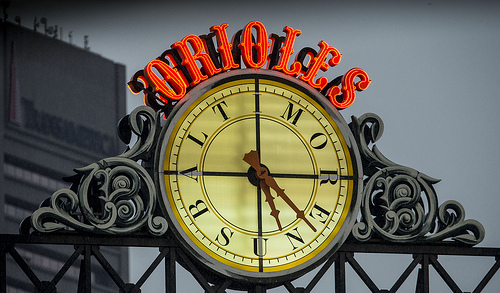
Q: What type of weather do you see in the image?
A: It is cloudy.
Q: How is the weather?
A: It is cloudy.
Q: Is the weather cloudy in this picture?
A: Yes, it is cloudy.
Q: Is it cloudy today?
A: Yes, it is cloudy.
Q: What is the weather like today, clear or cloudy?
A: It is cloudy.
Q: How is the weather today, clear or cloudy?
A: It is cloudy.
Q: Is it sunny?
A: No, it is cloudy.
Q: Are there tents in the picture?
A: No, there are no tents.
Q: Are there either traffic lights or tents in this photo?
A: No, there are no tents or traffic lights.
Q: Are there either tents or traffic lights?
A: No, there are no tents or traffic lights.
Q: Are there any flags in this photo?
A: No, there are no flags.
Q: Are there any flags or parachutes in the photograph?
A: No, there are no flags or parachutes.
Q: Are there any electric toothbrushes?
A: No, there are no electric toothbrushes.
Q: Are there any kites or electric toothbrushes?
A: No, there are no electric toothbrushes or kites.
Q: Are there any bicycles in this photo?
A: No, there are no bicycles.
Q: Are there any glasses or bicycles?
A: No, there are no bicycles or glasses.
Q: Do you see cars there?
A: No, there are no cars.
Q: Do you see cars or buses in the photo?
A: No, there are no cars or buses.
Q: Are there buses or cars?
A: No, there are no cars or buses.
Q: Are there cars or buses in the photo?
A: No, there are no cars or buses.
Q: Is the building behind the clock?
A: Yes, the building is behind the clock.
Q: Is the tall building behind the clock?
A: Yes, the building is behind the clock.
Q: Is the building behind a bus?
A: No, the building is behind the clock.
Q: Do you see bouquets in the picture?
A: No, there are no bouquets.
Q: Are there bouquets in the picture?
A: No, there are no bouquets.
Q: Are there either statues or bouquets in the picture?
A: No, there are no bouquets or statues.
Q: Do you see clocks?
A: Yes, there is a clock.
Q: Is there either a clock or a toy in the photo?
A: Yes, there is a clock.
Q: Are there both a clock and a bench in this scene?
A: No, there is a clock but no benches.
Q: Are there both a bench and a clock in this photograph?
A: No, there is a clock but no benches.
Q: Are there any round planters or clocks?
A: Yes, there is a round clock.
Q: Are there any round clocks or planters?
A: Yes, there is a round clock.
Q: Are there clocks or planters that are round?
A: Yes, the clock is round.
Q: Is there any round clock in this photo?
A: Yes, there is a round clock.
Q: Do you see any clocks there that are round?
A: Yes, there is a clock that is round.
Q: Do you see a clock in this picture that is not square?
A: Yes, there is a round clock.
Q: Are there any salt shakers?
A: No, there are no salt shakers.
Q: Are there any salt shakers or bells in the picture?
A: No, there are no salt shakers or bells.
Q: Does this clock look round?
A: Yes, the clock is round.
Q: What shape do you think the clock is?
A: The clock is round.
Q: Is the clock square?
A: No, the clock is round.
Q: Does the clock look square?
A: No, the clock is round.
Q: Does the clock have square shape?
A: No, the clock is round.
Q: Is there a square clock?
A: No, there is a clock but it is round.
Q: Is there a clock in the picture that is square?
A: No, there is a clock but it is round.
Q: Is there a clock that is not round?
A: No, there is a clock but it is round.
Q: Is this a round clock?
A: Yes, this is a round clock.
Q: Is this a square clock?
A: No, this is a round clock.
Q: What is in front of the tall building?
A: The clock is in front of the building.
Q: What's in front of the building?
A: The clock is in front of the building.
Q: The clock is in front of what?
A: The clock is in front of the building.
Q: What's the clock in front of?
A: The clock is in front of the building.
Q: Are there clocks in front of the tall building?
A: Yes, there is a clock in front of the building.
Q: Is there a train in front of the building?
A: No, there is a clock in front of the building.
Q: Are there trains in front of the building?
A: No, there is a clock in front of the building.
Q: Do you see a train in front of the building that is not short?
A: No, there is a clock in front of the building.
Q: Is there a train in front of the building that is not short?
A: No, there is a clock in front of the building.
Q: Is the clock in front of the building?
A: Yes, the clock is in front of the building.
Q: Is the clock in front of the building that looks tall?
A: Yes, the clock is in front of the building.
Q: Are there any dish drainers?
A: No, there are no dish drainers.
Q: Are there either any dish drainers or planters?
A: No, there are no dish drainers or planters.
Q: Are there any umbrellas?
A: No, there are no umbrellas.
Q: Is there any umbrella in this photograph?
A: No, there are no umbrellas.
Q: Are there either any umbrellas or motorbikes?
A: No, there are no umbrellas or motorbikes.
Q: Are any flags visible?
A: No, there are no flags.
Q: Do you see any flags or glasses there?
A: No, there are no flags or glasses.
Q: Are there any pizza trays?
A: No, there are no pizza trays.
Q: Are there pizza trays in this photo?
A: No, there are no pizza trays.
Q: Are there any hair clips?
A: No, there are no hair clips.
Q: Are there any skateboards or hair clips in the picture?
A: No, there are no hair clips or skateboards.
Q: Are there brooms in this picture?
A: No, there are no brooms.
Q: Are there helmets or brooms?
A: No, there are no brooms or helmets.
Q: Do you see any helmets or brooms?
A: No, there are no brooms or helmets.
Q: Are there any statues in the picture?
A: No, there are no statues.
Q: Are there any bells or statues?
A: No, there are no statues or bells.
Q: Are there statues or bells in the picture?
A: No, there are no statues or bells.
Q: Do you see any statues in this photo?
A: No, there are no statues.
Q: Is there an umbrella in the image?
A: No, there are no umbrellas.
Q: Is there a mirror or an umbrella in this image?
A: No, there are no umbrellas or mirrors.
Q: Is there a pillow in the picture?
A: No, there are no pillows.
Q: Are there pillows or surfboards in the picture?
A: No, there are no pillows or surfboards.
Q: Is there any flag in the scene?
A: No, there are no flags.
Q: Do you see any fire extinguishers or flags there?
A: No, there are no flags or fire extinguishers.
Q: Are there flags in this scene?
A: No, there are no flags.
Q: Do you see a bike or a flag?
A: No, there are no flags or bikes.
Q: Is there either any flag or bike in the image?
A: No, there are no flags or bikes.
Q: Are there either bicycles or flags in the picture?
A: No, there are no flags or bicycles.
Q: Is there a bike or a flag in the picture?
A: No, there are no flags or bikes.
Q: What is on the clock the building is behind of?
A: The letter is on the clock.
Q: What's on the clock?
A: The letter is on the clock.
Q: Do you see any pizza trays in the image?
A: No, there are no pizza trays.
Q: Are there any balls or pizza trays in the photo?
A: No, there are no pizza trays or balls.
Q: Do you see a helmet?
A: No, there are no helmets.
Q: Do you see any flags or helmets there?
A: No, there are no helmets or flags.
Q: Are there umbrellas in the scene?
A: No, there are no umbrellas.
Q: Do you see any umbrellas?
A: No, there are no umbrellas.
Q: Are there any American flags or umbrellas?
A: No, there are no umbrellas or American flags.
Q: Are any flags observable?
A: No, there are no flags.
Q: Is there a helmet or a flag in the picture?
A: No, there are no flags or helmets.